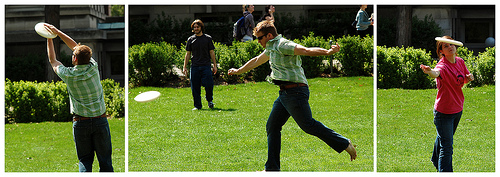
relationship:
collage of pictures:
[7, 5, 496, 175] [4, 6, 499, 176]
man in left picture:
[46, 31, 120, 176] [5, 5, 125, 175]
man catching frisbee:
[46, 31, 120, 176] [36, 22, 60, 42]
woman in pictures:
[431, 37, 468, 173] [373, 5, 498, 174]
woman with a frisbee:
[431, 37, 468, 173] [433, 37, 469, 50]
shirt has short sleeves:
[436, 59, 472, 113] [433, 62, 443, 78]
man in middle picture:
[245, 19, 357, 169] [129, 6, 373, 173]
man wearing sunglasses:
[245, 19, 357, 169] [254, 33, 266, 43]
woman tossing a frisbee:
[431, 37, 468, 173] [433, 37, 469, 50]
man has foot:
[245, 19, 357, 169] [346, 140, 362, 164]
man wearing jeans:
[245, 19, 357, 169] [268, 85, 348, 174]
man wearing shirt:
[181, 18, 223, 113] [183, 36, 216, 69]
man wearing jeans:
[181, 18, 223, 113] [190, 61, 220, 114]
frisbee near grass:
[133, 90, 161, 102] [132, 102, 263, 169]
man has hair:
[181, 18, 223, 113] [192, 20, 209, 27]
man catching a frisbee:
[46, 31, 120, 176] [36, 22, 60, 42]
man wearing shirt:
[46, 31, 120, 176] [61, 62, 111, 121]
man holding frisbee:
[46, 31, 120, 176] [36, 22, 60, 42]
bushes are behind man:
[132, 41, 377, 83] [181, 18, 223, 113]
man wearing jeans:
[46, 31, 120, 176] [71, 117, 116, 172]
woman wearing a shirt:
[431, 37, 468, 173] [436, 59, 472, 113]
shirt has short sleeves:
[61, 62, 111, 121] [55, 63, 74, 82]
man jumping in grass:
[245, 19, 357, 169] [132, 102, 263, 169]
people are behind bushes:
[234, 6, 375, 42] [132, 41, 377, 83]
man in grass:
[181, 18, 223, 113] [132, 102, 263, 169]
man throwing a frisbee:
[245, 19, 357, 169] [133, 90, 161, 102]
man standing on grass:
[181, 18, 223, 113] [132, 102, 263, 169]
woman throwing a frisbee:
[431, 37, 468, 173] [433, 37, 469, 50]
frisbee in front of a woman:
[433, 37, 469, 50] [431, 37, 468, 173]